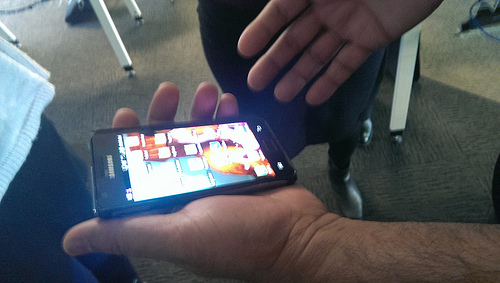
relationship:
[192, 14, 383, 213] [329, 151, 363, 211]
person wearing shoes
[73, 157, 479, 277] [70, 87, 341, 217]
man holding cell phone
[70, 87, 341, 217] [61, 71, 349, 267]
cell phone in hand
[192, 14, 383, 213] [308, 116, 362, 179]
person wearing tights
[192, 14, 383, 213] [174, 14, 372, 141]
person wearing a skirt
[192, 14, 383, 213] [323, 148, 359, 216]
person wearing a shoe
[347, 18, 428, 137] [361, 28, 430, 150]
object has leg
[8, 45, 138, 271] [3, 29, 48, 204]
person wearing a sweater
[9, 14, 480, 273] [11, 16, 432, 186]
room has a floor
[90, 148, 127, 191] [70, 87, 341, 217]
samsung on cell phone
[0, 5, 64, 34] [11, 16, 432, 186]
lamp on floor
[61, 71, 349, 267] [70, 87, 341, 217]
hand holding cell phone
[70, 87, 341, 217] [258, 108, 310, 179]
cell phone has buttons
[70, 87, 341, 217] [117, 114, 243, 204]
cell phone has a screen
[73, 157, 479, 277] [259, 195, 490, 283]
man has an arm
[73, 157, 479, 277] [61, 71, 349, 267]
man has a hand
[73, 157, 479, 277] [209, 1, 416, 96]
man has a right hand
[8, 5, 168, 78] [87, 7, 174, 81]
legs have wheels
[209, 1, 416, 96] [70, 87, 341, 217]
right hand pointing to cell phone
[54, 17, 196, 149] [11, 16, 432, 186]
shadows are on floor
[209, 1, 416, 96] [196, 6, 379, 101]
right hand has fingers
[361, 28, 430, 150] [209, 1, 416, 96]
leg behind right hand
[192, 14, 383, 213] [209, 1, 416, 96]
person behind right hand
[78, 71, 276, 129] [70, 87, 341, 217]
fingers are on cell phone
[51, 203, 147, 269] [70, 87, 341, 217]
thumb on cell phone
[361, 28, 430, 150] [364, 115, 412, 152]
leg has a wheel